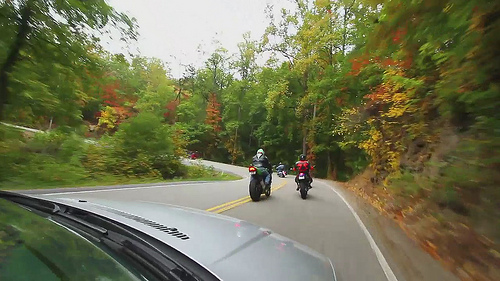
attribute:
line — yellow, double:
[214, 192, 261, 220]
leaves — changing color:
[352, 6, 487, 104]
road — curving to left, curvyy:
[2, 120, 462, 279]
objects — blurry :
[234, 130, 334, 209]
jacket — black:
[245, 155, 276, 166]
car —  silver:
[1, 180, 340, 279]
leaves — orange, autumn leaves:
[200, 89, 223, 131]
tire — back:
[247, 180, 262, 202]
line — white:
[362, 240, 404, 278]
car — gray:
[25, 92, 277, 274]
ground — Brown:
[343, 166, 500, 276]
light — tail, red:
[241, 164, 260, 175]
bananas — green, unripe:
[337, 170, 455, 270]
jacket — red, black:
[287, 154, 315, 177]